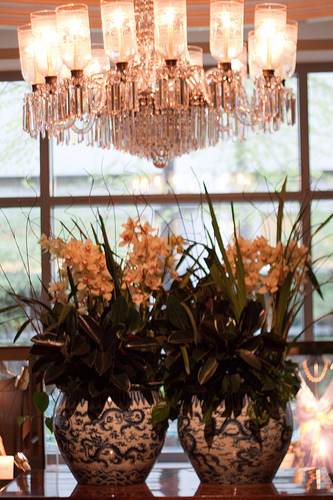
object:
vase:
[53, 384, 167, 486]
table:
[2, 470, 333, 498]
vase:
[178, 390, 292, 481]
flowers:
[79, 238, 101, 259]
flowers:
[258, 270, 279, 294]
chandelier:
[16, 0, 299, 168]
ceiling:
[1, 2, 332, 69]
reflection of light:
[20, 469, 313, 493]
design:
[72, 402, 149, 476]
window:
[1, 68, 333, 429]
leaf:
[110, 296, 131, 327]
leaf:
[31, 332, 64, 348]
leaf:
[89, 376, 109, 397]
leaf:
[130, 355, 154, 379]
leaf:
[32, 387, 52, 415]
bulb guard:
[154, 1, 188, 63]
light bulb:
[109, 8, 127, 41]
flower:
[46, 276, 67, 296]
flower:
[118, 217, 140, 249]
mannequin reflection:
[0, 349, 49, 499]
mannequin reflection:
[288, 349, 333, 488]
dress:
[293, 372, 332, 469]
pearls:
[300, 358, 328, 384]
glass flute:
[210, 2, 244, 62]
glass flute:
[254, 5, 286, 72]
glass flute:
[57, 2, 95, 73]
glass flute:
[30, 7, 64, 82]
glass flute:
[17, 22, 47, 92]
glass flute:
[283, 18, 299, 82]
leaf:
[113, 292, 130, 321]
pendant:
[94, 116, 108, 149]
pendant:
[58, 118, 71, 145]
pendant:
[206, 109, 219, 145]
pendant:
[197, 111, 211, 147]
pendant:
[170, 114, 186, 156]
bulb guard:
[99, 0, 138, 65]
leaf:
[206, 180, 236, 292]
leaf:
[272, 174, 288, 244]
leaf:
[308, 258, 325, 302]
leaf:
[12, 314, 35, 343]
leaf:
[198, 354, 220, 387]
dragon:
[79, 405, 145, 430]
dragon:
[81, 438, 142, 465]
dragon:
[199, 414, 262, 441]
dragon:
[193, 447, 229, 475]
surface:
[209, 409, 271, 474]